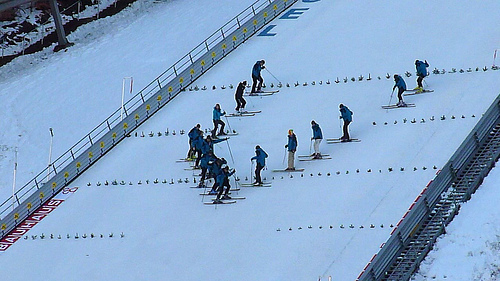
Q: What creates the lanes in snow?
A: Fences.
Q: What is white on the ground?
A: Snow.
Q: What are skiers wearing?
A: Blue jackets.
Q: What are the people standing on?
A: Skis.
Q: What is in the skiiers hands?
A: Poles.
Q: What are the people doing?
A: SNow skating.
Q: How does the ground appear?
A: Slanted.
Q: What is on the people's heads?
A: Hats.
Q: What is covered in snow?
A: Ski slope.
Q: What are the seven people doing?
A: Skiing.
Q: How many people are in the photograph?
A: Fifteen.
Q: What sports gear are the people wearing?
A: Skis.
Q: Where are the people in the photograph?
A: On a ski slope.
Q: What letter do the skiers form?
A: The letter V.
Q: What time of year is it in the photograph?
A: Winter.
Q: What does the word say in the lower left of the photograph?
A: BAUHAUS.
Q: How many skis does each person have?
A: Two.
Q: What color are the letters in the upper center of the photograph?
A: Blue.